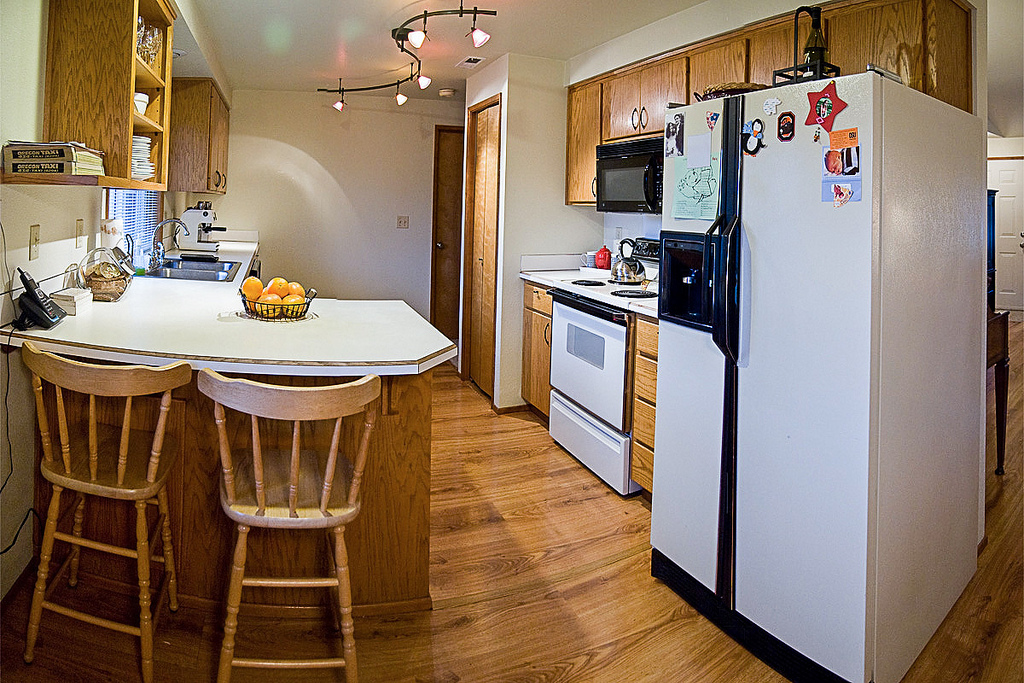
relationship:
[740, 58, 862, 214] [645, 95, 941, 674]
magnets on fridge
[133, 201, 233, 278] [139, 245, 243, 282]
faucet over sink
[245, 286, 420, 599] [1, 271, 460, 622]
chair under table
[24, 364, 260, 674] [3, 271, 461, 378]
chair under counter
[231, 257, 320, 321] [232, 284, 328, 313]
fruit in bowl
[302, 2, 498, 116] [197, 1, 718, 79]
lights on ceiling